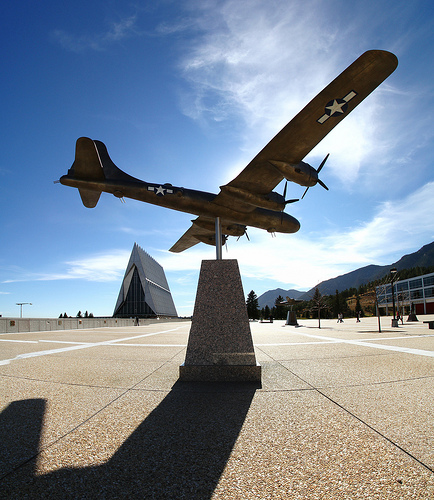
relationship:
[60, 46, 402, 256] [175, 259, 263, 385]
airplane on pedestal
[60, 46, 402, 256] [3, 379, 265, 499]
airplane has shadow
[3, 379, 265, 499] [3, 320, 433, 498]
shadow on ground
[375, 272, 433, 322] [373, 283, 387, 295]
building has window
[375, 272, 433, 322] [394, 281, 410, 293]
building has window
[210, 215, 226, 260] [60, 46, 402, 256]
pole holding airplane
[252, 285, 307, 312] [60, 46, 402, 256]
mountain behind airplane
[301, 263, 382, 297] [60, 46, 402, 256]
mountain behind airplane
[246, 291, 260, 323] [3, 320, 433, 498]
tree planted in ground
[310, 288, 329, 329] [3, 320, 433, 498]
tree planted in ground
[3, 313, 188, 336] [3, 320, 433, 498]
wall next to ground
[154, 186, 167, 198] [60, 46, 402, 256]
star on side of airplane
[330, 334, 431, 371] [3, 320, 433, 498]
line on ground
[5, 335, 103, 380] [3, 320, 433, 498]
line on ground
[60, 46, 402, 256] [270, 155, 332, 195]
airplane has propeller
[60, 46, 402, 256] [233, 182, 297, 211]
airplane has propeller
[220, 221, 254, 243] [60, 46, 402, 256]
propeller on front of airplane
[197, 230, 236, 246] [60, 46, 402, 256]
propeller on front of airplane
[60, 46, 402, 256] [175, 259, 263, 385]
airplane on top of pedestal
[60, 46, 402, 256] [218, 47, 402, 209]
airplane has wing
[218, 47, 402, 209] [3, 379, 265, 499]
wing has shadow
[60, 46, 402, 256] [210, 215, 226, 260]
airplane on top of pole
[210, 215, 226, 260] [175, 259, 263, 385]
pole on top of pedestal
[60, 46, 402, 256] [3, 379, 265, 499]
airplane making shadow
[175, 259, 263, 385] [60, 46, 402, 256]
pedestal underneath airplane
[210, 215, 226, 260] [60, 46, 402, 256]
pole underneath airplane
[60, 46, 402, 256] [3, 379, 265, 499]
airplane casting shadow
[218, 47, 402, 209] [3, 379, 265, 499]
wing casting shadow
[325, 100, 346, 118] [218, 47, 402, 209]
star on wing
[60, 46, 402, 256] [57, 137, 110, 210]
airplane has tail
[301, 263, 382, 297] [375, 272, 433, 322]
mountain behind building